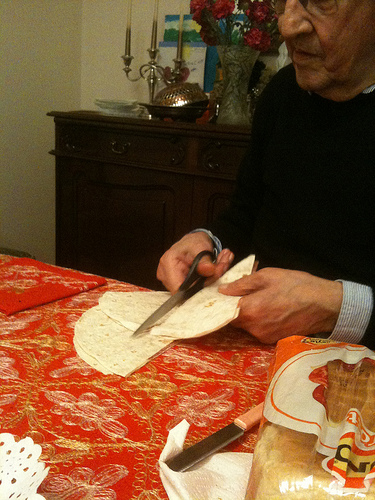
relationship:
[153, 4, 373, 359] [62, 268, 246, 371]
man cutting tortillas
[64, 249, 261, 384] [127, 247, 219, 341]
tortillas with scissors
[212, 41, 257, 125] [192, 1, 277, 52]
vase with flowers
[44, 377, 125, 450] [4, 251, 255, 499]
design on tablecloth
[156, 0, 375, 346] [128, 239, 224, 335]
man holding scissors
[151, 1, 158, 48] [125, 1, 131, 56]
candle with candlestick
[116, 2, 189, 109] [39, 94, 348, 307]
candleabra on chest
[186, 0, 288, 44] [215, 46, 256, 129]
flowers on vase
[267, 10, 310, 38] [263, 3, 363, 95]
man's nose on face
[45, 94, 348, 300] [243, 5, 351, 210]
chest behind man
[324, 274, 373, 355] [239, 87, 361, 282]
cuff on shirt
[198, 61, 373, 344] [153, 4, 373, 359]
sweater on man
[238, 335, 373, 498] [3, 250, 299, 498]
bread on table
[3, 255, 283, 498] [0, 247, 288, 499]
stitching on tablecloth